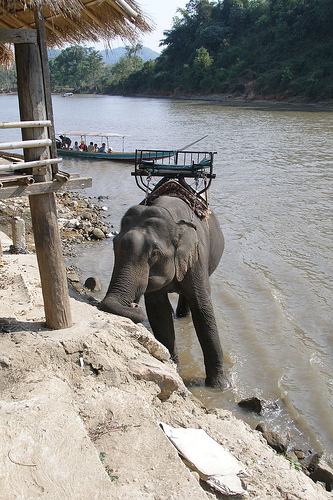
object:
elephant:
[98, 188, 231, 393]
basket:
[131, 151, 218, 207]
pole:
[13, 41, 76, 331]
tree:
[251, 21, 273, 49]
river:
[246, 129, 284, 170]